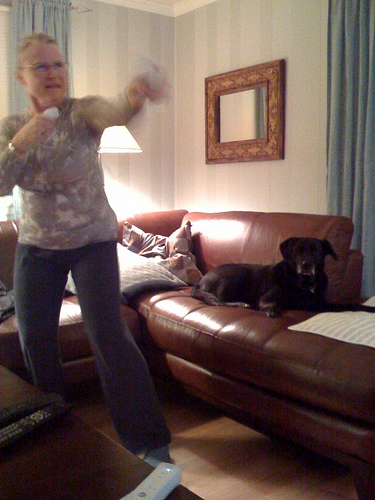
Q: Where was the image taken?
A: It was taken at the living room.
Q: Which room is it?
A: It is a living room.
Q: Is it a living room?
A: Yes, it is a living room.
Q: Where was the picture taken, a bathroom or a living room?
A: It was taken at a living room.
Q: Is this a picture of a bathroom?
A: No, the picture is showing a living room.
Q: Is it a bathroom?
A: No, it is a living room.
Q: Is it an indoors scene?
A: Yes, it is indoors.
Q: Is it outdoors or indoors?
A: It is indoors.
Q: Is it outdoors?
A: No, it is indoors.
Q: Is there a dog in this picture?
A: Yes, there is a dog.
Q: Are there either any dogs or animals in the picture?
A: Yes, there is a dog.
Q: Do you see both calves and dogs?
A: No, there is a dog but no calves.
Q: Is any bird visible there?
A: No, there are no birds.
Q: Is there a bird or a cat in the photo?
A: No, there are no birds or cats.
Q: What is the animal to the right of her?
A: The animal is a dog.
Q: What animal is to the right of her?
A: The animal is a dog.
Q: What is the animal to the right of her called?
A: The animal is a dog.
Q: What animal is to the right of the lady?
A: The animal is a dog.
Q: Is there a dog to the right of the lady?
A: Yes, there is a dog to the right of the lady.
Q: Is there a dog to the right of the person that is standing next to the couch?
A: Yes, there is a dog to the right of the lady.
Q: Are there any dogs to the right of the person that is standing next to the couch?
A: Yes, there is a dog to the right of the lady.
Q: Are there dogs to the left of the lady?
A: No, the dog is to the right of the lady.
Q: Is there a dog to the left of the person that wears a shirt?
A: No, the dog is to the right of the lady.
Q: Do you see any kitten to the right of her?
A: No, there is a dog to the right of the lady.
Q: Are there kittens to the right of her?
A: No, there is a dog to the right of the lady.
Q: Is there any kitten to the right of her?
A: No, there is a dog to the right of the lady.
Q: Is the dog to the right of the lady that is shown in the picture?
A: Yes, the dog is to the right of the lady.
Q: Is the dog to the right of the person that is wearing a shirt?
A: Yes, the dog is to the right of the lady.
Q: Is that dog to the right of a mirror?
A: No, the dog is to the right of the lady.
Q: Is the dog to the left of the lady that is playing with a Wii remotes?
A: No, the dog is to the right of the lady.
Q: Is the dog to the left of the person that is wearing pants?
A: No, the dog is to the right of the lady.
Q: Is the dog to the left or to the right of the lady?
A: The dog is to the right of the lady.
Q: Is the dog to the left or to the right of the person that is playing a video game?
A: The dog is to the right of the lady.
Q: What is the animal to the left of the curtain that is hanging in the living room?
A: The animal is a dog.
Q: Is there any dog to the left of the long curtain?
A: Yes, there is a dog to the left of the curtain.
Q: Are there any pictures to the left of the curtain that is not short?
A: No, there is a dog to the left of the curtain.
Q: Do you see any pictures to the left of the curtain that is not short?
A: No, there is a dog to the left of the curtain.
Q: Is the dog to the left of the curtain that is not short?
A: Yes, the dog is to the left of the curtain.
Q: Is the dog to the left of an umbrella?
A: No, the dog is to the left of the curtain.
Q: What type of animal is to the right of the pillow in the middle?
A: The animal is a dog.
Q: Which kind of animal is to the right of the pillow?
A: The animal is a dog.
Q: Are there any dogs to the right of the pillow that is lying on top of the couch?
A: Yes, there is a dog to the right of the pillow.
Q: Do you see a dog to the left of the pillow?
A: No, the dog is to the right of the pillow.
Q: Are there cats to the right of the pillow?
A: No, there is a dog to the right of the pillow.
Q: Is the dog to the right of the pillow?
A: Yes, the dog is to the right of the pillow.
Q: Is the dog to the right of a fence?
A: No, the dog is to the right of the pillow.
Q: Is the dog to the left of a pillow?
A: No, the dog is to the right of a pillow.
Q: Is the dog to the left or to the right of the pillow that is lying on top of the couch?
A: The dog is to the right of the pillow.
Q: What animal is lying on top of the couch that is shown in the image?
A: The animal is a dog.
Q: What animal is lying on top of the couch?
A: The animal is a dog.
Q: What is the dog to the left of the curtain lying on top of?
A: The dog is lying on top of the couch.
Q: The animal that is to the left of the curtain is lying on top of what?
A: The dog is lying on top of the couch.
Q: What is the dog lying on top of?
A: The dog is lying on top of the couch.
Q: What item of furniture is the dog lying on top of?
A: The dog is lying on top of the couch.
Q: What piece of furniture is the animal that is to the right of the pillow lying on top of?
A: The dog is lying on top of the couch.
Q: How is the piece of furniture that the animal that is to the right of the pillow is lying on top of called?
A: The piece of furniture is a couch.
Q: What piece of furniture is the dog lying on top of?
A: The dog is lying on top of the couch.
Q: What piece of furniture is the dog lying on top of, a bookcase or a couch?
A: The dog is lying on top of a couch.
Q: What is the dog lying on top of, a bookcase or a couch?
A: The dog is lying on top of a couch.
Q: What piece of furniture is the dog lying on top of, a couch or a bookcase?
A: The dog is lying on top of a couch.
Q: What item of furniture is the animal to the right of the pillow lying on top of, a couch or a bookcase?
A: The dog is lying on top of a couch.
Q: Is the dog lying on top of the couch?
A: Yes, the dog is lying on top of the couch.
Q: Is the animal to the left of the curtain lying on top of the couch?
A: Yes, the dog is lying on top of the couch.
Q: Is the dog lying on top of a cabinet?
A: No, the dog is lying on top of the couch.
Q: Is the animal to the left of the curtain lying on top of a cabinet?
A: No, the dog is lying on top of the couch.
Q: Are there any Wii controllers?
A: Yes, there is a Wii controller.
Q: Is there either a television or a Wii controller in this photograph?
A: Yes, there is a Wii controller.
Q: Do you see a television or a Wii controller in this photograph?
A: Yes, there is a Wii controller.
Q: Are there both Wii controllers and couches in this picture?
A: Yes, there are both a Wii controller and a couch.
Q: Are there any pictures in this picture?
A: No, there are no pictures.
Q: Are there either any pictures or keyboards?
A: No, there are no pictures or keyboards.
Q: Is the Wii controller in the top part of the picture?
A: Yes, the Wii controller is in the top of the image.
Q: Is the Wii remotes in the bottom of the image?
A: No, the Wii remotes is in the top of the image.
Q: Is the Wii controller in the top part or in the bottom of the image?
A: The Wii controller is in the top of the image.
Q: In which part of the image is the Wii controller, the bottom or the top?
A: The Wii controller is in the top of the image.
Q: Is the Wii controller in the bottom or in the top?
A: The Wii controller is in the top of the image.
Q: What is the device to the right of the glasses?
A: The device is a Wii controller.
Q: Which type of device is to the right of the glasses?
A: The device is a Wii controller.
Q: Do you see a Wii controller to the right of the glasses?
A: Yes, there is a Wii controller to the right of the glasses.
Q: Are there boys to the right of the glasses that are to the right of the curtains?
A: No, there is a Wii controller to the right of the glasses.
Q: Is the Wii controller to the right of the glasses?
A: Yes, the Wii controller is to the right of the glasses.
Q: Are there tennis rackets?
A: No, there are no tennis rackets.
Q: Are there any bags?
A: No, there are no bags.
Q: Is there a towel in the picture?
A: Yes, there is a towel.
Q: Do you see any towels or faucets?
A: Yes, there is a towel.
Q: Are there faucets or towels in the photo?
A: Yes, there is a towel.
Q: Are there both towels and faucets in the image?
A: No, there is a towel but no faucets.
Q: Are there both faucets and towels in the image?
A: No, there is a towel but no faucets.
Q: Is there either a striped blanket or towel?
A: Yes, there is a striped towel.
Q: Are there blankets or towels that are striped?
A: Yes, the towel is striped.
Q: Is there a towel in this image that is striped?
A: Yes, there is a striped towel.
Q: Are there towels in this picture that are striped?
A: Yes, there is a towel that is striped.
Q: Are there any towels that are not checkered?
A: Yes, there is a striped towel.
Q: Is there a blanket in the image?
A: No, there are no blankets.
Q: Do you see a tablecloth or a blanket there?
A: No, there are no blankets or tablecloths.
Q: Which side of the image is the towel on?
A: The towel is on the right of the image.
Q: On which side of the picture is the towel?
A: The towel is on the right of the image.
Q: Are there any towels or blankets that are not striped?
A: No, there is a towel but it is striped.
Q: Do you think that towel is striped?
A: Yes, the towel is striped.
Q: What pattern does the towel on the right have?
A: The towel has striped pattern.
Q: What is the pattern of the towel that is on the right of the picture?
A: The towel is striped.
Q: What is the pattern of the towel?
A: The towel is striped.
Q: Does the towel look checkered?
A: No, the towel is striped.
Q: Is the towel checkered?
A: No, the towel is striped.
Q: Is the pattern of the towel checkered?
A: No, the towel is striped.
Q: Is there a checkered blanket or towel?
A: No, there is a towel but it is striped.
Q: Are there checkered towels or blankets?
A: No, there is a towel but it is striped.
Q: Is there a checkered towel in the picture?
A: No, there is a towel but it is striped.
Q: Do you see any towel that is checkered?
A: No, there is a towel but it is striped.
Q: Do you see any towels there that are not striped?
A: No, there is a towel but it is striped.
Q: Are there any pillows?
A: Yes, there is a pillow.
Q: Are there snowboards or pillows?
A: Yes, there is a pillow.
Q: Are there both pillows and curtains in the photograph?
A: Yes, there are both a pillow and a curtain.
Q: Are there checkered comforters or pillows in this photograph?
A: Yes, there is a checkered pillow.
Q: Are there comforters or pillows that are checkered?
A: Yes, the pillow is checkered.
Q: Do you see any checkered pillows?
A: Yes, there is a checkered pillow.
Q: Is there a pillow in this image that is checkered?
A: Yes, there is a pillow that is checkered.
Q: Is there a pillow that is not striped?
A: Yes, there is a checkered pillow.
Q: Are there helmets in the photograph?
A: No, there are no helmets.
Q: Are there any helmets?
A: No, there are no helmets.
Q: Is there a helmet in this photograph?
A: No, there are no helmets.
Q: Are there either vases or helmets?
A: No, there are no helmets or vases.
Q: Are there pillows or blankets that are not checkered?
A: No, there is a pillow but it is checkered.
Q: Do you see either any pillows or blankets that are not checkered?
A: No, there is a pillow but it is checkered.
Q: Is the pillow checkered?
A: Yes, the pillow is checkered.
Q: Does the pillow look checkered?
A: Yes, the pillow is checkered.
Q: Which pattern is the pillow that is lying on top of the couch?
A: The pillow is checkered.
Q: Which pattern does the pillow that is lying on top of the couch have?
A: The pillow has checkered pattern.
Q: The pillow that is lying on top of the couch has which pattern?
A: The pillow is checkered.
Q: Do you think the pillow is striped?
A: No, the pillow is checkered.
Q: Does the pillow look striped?
A: No, the pillow is checkered.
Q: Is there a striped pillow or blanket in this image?
A: No, there is a pillow but it is checkered.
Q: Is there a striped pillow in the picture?
A: No, there is a pillow but it is checkered.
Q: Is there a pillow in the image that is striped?
A: No, there is a pillow but it is checkered.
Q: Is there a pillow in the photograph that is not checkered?
A: No, there is a pillow but it is checkered.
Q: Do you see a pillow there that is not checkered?
A: No, there is a pillow but it is checkered.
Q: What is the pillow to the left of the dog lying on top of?
A: The pillow is lying on top of the couch.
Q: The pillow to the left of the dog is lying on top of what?
A: The pillow is lying on top of the couch.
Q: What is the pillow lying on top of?
A: The pillow is lying on top of the couch.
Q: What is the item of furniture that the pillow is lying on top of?
A: The piece of furniture is a couch.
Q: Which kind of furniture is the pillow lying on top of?
A: The pillow is lying on top of the couch.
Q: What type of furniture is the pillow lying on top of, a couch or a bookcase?
A: The pillow is lying on top of a couch.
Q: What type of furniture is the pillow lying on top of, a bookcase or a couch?
A: The pillow is lying on top of a couch.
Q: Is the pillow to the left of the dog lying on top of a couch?
A: Yes, the pillow is lying on top of a couch.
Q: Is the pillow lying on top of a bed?
A: No, the pillow is lying on top of a couch.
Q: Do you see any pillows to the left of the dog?
A: Yes, there is a pillow to the left of the dog.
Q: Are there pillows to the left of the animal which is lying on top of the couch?
A: Yes, there is a pillow to the left of the dog.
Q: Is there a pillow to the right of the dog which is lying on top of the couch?
A: No, the pillow is to the left of the dog.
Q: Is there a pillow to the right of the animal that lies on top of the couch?
A: No, the pillow is to the left of the dog.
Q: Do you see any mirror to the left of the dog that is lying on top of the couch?
A: No, there is a pillow to the left of the dog.